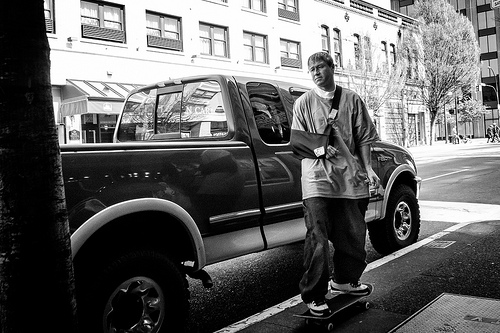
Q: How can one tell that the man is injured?
A: He is wearing a sling.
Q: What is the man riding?
A: Skateboard.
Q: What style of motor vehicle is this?
A: A pick-up.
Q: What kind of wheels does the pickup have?
A: Chrome.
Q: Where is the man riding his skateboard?
A: On the sidewalk.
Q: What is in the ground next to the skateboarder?
A: A utility vault.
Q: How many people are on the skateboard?
A: One.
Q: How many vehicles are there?
A: One.